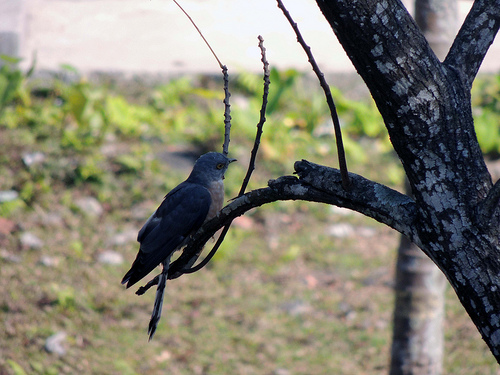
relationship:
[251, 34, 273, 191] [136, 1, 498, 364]
branch on tree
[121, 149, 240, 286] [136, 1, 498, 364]
bird on a tree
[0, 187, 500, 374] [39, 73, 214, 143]
grass are in background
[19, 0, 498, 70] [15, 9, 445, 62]
building in background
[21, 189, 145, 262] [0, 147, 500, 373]
rocks are in grass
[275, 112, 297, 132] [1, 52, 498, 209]
yellow leaf in weeds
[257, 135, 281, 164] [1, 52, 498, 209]
yellow leaf in weeds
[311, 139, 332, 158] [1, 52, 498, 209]
yellow leaf in weeds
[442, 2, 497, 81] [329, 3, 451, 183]
limb growing off limb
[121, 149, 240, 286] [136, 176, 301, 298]
bird perched on limb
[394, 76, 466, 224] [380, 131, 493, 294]
splotches are on tree trunk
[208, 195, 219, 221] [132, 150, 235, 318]
chest on bird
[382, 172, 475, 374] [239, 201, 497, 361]
trunk in background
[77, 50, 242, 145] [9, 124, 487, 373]
grass on ground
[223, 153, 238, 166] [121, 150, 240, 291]
beak on bird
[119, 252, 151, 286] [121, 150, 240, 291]
tail feather on bird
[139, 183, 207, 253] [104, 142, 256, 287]
wing on bird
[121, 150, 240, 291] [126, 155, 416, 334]
bird on branch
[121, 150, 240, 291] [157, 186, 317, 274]
bird on branch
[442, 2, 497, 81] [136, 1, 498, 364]
limb attached to tree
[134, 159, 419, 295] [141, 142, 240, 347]
branch holding bird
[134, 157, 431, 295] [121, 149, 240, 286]
branch holding bird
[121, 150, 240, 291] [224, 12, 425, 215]
bird on branch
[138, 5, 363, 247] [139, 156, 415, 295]
twigs on limb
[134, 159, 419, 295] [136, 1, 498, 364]
branch attached to tree